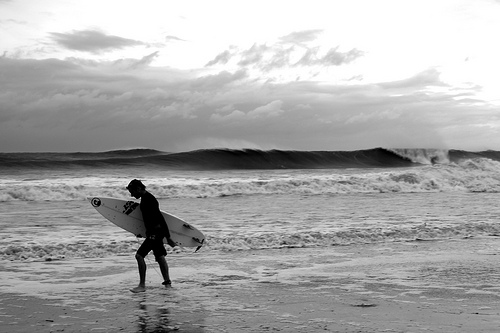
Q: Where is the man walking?
A: On beach.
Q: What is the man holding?
A: Surfboard.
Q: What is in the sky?
A: Clouds.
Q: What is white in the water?
A: Waves.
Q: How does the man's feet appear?
A: Barefoot.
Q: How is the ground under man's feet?
A: Sandy.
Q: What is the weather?
A: Mostly cloudy.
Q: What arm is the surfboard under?
A: Right.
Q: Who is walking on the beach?
A: The man with surfboard.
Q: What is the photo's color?
A: Black and white.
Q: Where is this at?
A: Ocean.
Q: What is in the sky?
A: Clouds.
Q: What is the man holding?
A: Surfboard.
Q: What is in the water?
A: Waves.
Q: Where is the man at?
A: Shoreline.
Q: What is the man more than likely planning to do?
A: Surfing.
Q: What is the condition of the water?
A: Choppy.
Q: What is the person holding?
A: A surfboard.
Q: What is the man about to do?
A: Go surfing.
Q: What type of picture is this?
A: Black and white.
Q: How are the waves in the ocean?
A: Rough.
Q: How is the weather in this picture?
A: Cloudy.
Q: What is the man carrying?
A: A surfboard.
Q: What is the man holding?
A: A surfboard.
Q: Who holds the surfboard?
A: The man.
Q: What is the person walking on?
A: Sand.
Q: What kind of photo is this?
A: Black and white.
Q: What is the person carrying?
A: Surfboard.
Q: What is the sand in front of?
A: Body of water.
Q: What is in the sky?
A: Clouds.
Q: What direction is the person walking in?
A: Left.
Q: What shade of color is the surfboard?
A: White.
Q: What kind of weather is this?
A: Overcast.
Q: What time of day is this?
A: Daylight hours.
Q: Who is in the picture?
A: A man.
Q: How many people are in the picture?
A: One.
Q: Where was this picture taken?
A: The beach.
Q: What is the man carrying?
A: Surfboard.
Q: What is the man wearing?
A: Wetsuit.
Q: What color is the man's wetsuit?
A: Black.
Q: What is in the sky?
A: Clouds.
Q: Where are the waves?
A: The ocean.